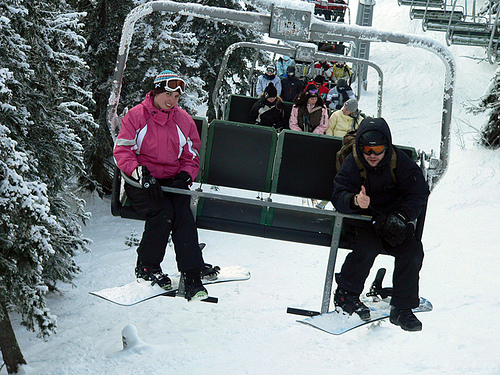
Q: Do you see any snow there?
A: Yes, there is snow.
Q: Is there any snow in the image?
A: Yes, there is snow.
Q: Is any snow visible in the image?
A: Yes, there is snow.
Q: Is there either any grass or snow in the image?
A: Yes, there is snow.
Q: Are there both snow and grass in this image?
A: No, there is snow but no grass.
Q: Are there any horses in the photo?
A: No, there are no horses.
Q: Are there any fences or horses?
A: No, there are no horses or fences.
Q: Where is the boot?
A: The boot is on the snow.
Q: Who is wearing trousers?
A: The lady is wearing trousers.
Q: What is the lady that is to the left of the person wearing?
A: The lady is wearing pants.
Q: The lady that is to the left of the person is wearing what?
A: The lady is wearing pants.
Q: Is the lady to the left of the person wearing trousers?
A: Yes, the lady is wearing trousers.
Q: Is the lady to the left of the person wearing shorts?
A: No, the lady is wearing trousers.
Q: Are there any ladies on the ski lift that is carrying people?
A: Yes, there is a lady on the ski lift.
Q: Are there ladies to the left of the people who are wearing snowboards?
A: Yes, there is a lady to the left of the people.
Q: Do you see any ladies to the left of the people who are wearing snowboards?
A: Yes, there is a lady to the left of the people.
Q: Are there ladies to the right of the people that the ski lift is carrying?
A: No, the lady is to the left of the people.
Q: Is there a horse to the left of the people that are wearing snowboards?
A: No, there is a lady to the left of the people.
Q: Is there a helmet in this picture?
A: No, there are no helmets.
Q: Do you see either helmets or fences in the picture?
A: No, there are no helmets or fences.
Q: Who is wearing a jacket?
A: The lady is wearing a jacket.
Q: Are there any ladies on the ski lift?
A: Yes, there is a lady on the ski lift.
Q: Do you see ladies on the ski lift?
A: Yes, there is a lady on the ski lift.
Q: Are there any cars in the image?
A: No, there are no cars.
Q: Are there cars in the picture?
A: No, there are no cars.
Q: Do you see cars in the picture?
A: No, there are no cars.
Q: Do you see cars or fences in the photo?
A: No, there are no cars or fences.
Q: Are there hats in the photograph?
A: Yes, there is a hat.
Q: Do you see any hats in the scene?
A: Yes, there is a hat.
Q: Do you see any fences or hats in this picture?
A: Yes, there is a hat.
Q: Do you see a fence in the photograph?
A: No, there are no fences.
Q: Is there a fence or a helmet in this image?
A: No, there are no fences or helmets.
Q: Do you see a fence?
A: No, there are no fences.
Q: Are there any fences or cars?
A: No, there are no fences or cars.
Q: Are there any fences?
A: No, there are no fences.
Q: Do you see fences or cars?
A: No, there are no fences or cars.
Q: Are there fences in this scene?
A: No, there are no fences.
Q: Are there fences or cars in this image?
A: No, there are no fences or cars.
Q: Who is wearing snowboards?
A: The people are wearing snowboards.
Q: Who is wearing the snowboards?
A: The people are wearing snowboards.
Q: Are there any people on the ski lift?
A: Yes, there are people on the ski lift.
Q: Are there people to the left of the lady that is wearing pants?
A: No, the people are to the right of the lady.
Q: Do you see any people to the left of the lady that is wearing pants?
A: No, the people are to the right of the lady.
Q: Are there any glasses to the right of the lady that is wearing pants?
A: No, there are people to the right of the lady.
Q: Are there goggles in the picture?
A: Yes, there are goggles.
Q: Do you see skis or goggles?
A: Yes, there are goggles.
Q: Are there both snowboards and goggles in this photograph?
A: Yes, there are both goggles and a snowboard.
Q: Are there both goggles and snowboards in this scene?
A: Yes, there are both goggles and a snowboard.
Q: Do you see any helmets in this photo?
A: No, there are no helmets.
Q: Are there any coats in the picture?
A: Yes, there is a coat.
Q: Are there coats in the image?
A: Yes, there is a coat.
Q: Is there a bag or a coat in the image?
A: Yes, there is a coat.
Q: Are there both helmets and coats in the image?
A: No, there is a coat but no helmets.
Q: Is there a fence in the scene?
A: No, there are no fences.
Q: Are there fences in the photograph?
A: No, there are no fences.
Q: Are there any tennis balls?
A: No, there are no tennis balls.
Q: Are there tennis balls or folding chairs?
A: No, there are no tennis balls or folding chairs.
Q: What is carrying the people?
A: The ski lift is carrying the people.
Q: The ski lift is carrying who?
A: The ski lift is carrying people.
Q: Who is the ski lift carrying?
A: The ski lift is carrying people.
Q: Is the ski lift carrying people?
A: Yes, the ski lift is carrying people.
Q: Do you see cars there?
A: No, there are no cars.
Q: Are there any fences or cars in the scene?
A: No, there are no cars or fences.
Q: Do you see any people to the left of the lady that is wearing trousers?
A: No, the person is to the right of the lady.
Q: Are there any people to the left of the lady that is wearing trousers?
A: No, the person is to the right of the lady.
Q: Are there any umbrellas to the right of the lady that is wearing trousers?
A: No, there is a person to the right of the lady.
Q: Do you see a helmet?
A: No, there are no helmets.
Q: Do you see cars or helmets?
A: No, there are no helmets or cars.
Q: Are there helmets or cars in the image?
A: No, there are no helmets or cars.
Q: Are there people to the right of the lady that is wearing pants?
A: Yes, there is a person to the right of the lady.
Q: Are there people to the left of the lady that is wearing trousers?
A: No, the person is to the right of the lady.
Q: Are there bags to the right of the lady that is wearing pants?
A: No, there is a person to the right of the lady.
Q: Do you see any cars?
A: No, there are no cars.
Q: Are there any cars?
A: No, there are no cars.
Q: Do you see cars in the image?
A: No, there are no cars.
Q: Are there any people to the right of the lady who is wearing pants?
A: Yes, there is a person to the right of the lady.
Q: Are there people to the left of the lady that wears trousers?
A: No, the person is to the right of the lady.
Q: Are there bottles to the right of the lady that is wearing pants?
A: No, there is a person to the right of the lady.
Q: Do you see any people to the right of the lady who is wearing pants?
A: Yes, there is a person to the right of the lady.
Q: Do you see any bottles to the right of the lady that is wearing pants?
A: No, there is a person to the right of the lady.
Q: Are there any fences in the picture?
A: No, there are no fences.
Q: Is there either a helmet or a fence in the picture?
A: No, there are no fences or helmets.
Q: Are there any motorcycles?
A: No, there are no motorcycles.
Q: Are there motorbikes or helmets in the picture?
A: No, there are no motorbikes or helmets.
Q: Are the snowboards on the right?
A: Yes, the snowboards are on the right of the image.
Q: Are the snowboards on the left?
A: No, the snowboards are on the right of the image.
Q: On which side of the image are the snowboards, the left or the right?
A: The snowboards are on the right of the image.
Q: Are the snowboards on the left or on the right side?
A: The snowboards are on the right of the image.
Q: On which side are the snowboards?
A: The snowboards are on the right of the image.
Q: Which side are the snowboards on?
A: The snowboards are on the right of the image.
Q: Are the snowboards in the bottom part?
A: Yes, the snowboards are in the bottom of the image.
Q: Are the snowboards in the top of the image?
A: No, the snowboards are in the bottom of the image.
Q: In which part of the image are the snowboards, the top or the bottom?
A: The snowboards are in the bottom of the image.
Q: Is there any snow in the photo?
A: Yes, there is snow.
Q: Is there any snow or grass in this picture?
A: Yes, there is snow.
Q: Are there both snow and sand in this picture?
A: No, there is snow but no sand.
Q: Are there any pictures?
A: No, there are no pictures.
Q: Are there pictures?
A: No, there are no pictures.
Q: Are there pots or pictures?
A: No, there are no pictures or pots.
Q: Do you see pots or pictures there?
A: No, there are no pictures or pots.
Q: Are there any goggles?
A: Yes, there are goggles.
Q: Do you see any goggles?
A: Yes, there are goggles.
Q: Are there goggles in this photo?
A: Yes, there are goggles.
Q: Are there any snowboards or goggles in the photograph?
A: Yes, there are goggles.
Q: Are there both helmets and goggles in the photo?
A: No, there are goggles but no helmets.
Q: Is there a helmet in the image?
A: No, there are no helmets.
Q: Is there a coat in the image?
A: Yes, there is a coat.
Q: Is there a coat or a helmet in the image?
A: Yes, there is a coat.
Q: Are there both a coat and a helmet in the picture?
A: No, there is a coat but no helmets.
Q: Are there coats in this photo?
A: Yes, there is a coat.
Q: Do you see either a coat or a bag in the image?
A: Yes, there is a coat.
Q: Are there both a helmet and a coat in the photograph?
A: No, there is a coat but no helmets.